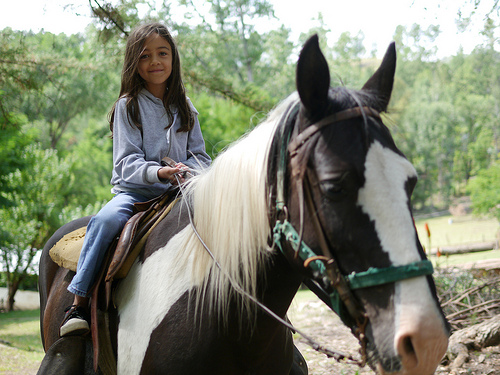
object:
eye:
[318, 181, 349, 202]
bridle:
[161, 157, 364, 366]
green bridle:
[272, 130, 433, 317]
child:
[59, 22, 212, 337]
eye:
[158, 50, 168, 57]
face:
[136, 32, 172, 85]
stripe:
[356, 139, 448, 337]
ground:
[393, 199, 406, 215]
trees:
[0, 0, 500, 256]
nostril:
[398, 335, 418, 366]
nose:
[396, 326, 449, 375]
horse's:
[46, 190, 175, 374]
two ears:
[295, 33, 397, 110]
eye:
[140, 54, 149, 59]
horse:
[37, 32, 452, 375]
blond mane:
[169, 90, 300, 340]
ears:
[296, 33, 331, 107]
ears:
[360, 41, 397, 109]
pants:
[66, 192, 151, 298]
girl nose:
[149, 51, 161, 67]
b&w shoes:
[59, 304, 90, 337]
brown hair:
[106, 22, 194, 139]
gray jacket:
[110, 88, 212, 199]